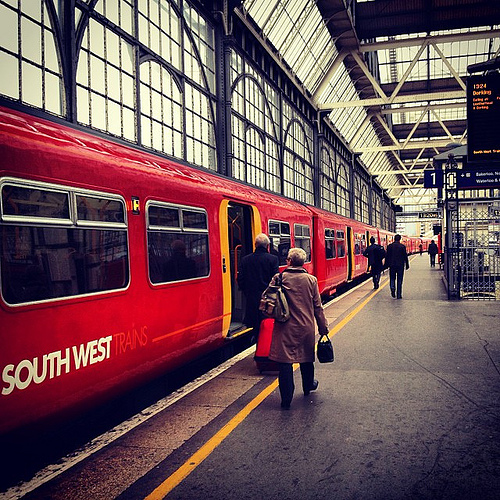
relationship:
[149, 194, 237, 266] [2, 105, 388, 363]
window on train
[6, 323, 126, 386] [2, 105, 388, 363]
logo on train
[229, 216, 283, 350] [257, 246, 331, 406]
man ahead of lady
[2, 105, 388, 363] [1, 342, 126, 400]
train has lettering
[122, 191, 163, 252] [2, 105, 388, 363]
light on train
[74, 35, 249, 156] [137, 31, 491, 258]
window of station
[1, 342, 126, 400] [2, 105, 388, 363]
lettering of train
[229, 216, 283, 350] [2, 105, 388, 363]
man on train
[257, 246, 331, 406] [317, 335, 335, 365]
lady with handbag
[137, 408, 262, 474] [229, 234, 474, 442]
line on floor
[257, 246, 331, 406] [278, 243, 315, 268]
lady has head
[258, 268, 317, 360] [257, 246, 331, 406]
coat on lady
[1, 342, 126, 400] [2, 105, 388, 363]
writing on train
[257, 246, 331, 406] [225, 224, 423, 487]
lady on sidewalk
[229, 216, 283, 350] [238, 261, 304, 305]
man has jacket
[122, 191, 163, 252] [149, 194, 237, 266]
light between window